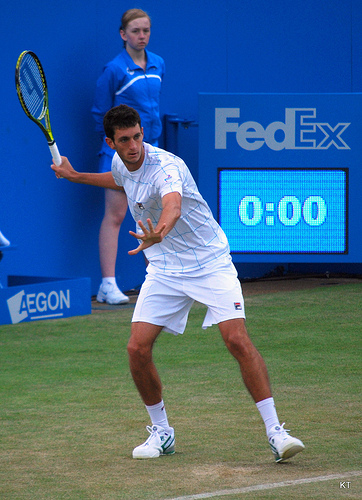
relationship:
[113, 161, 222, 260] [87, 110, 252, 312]
shirt on man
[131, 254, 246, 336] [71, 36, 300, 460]
shorts on man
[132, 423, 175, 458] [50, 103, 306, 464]
shoe on man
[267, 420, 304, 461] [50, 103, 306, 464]
shoe on man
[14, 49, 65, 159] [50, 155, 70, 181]
racket in hand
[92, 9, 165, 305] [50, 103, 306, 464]
woman standing behind man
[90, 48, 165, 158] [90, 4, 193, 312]
blue jacket on woman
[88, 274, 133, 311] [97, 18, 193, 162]
shoe on woman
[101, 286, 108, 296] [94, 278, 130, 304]
nike logo on shoe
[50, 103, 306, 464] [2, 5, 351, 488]
man on a tennis court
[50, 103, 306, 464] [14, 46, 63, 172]
man swinging racket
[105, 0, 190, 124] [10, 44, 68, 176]
man swinging racket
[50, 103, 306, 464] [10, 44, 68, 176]
man holding racket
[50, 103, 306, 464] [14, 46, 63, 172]
man holding racket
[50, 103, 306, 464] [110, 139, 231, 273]
man wearing shirt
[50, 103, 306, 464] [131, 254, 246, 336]
man wearing shorts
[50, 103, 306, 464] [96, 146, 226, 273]
man wearing shirt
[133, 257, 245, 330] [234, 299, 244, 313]
shorts displays logo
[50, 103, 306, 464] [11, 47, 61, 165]
man holding racket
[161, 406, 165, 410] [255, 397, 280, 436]
label on sock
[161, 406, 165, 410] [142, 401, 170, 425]
label on white sock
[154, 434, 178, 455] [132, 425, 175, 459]
stripes on shoe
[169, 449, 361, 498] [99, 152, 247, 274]
line on shirt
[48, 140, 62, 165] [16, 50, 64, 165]
white grip on racket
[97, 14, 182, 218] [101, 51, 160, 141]
woman wearing blue jacket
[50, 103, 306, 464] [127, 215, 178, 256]
man extending hand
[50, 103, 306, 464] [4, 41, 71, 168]
man holding racket